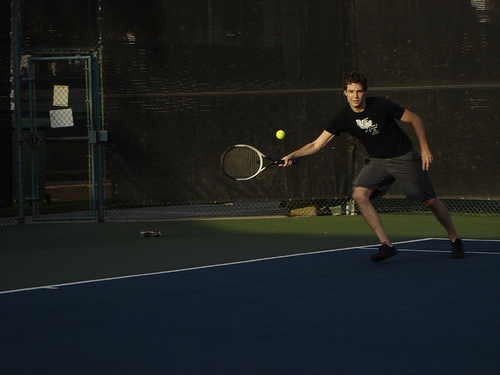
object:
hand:
[278, 157, 293, 168]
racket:
[219, 143, 298, 181]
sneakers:
[450, 236, 465, 259]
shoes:
[370, 241, 398, 263]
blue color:
[217, 277, 358, 338]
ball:
[275, 130, 286, 140]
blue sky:
[268, 117, 286, 127]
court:
[0, 209, 500, 375]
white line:
[1, 238, 436, 292]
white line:
[431, 237, 500, 242]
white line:
[361, 245, 498, 253]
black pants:
[114, 85, 219, 165]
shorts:
[354, 149, 437, 201]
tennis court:
[0, 235, 500, 375]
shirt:
[324, 96, 414, 158]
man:
[275, 69, 465, 261]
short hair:
[343, 70, 367, 91]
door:
[12, 52, 101, 222]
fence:
[103, 83, 498, 223]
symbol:
[355, 117, 379, 136]